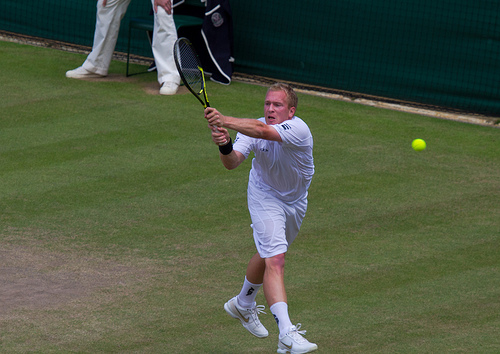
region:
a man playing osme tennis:
[166, 41, 347, 351]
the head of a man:
[256, 82, 293, 132]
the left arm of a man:
[216, 106, 316, 153]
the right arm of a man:
[208, 125, 258, 174]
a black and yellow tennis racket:
[162, 37, 229, 113]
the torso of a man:
[230, 130, 331, 204]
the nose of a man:
[266, 104, 278, 113]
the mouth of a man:
[264, 112, 278, 119]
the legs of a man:
[223, 252, 317, 324]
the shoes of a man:
[216, 289, 291, 351]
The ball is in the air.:
[407, 129, 432, 155]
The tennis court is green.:
[366, 245, 487, 343]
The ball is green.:
[409, 132, 427, 157]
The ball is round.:
[404, 129, 429, 153]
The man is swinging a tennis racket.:
[164, 35, 315, 156]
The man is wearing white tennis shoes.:
[224, 275, 322, 352]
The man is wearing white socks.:
[224, 274, 321, 352]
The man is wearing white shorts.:
[241, 174, 316, 259]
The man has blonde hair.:
[258, 76, 300, 123]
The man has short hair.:
[257, 77, 299, 124]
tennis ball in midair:
[409, 136, 429, 153]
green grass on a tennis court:
[321, 150, 499, 352]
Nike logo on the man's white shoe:
[228, 304, 254, 326]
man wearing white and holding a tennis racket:
[173, 34, 318, 350]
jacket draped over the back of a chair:
[192, 0, 237, 85]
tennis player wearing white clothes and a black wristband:
[205, 83, 319, 349]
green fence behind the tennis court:
[241, 0, 498, 75]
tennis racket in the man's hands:
[170, 37, 228, 146]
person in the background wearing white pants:
[62, 0, 182, 97]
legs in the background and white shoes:
[63, 0, 183, 98]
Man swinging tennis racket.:
[6, 3, 498, 350]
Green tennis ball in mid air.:
[407, 130, 427, 156]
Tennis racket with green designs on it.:
[171, 32, 212, 142]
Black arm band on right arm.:
[207, 109, 245, 173]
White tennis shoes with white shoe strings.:
[218, 290, 322, 351]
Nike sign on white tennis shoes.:
[220, 292, 268, 349]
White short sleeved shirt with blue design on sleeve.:
[228, 102, 330, 202]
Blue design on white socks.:
[238, 272, 309, 329]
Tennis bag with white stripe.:
[194, 2, 246, 84]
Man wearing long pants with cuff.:
[68, 0, 185, 98]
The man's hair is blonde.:
[261, 80, 300, 125]